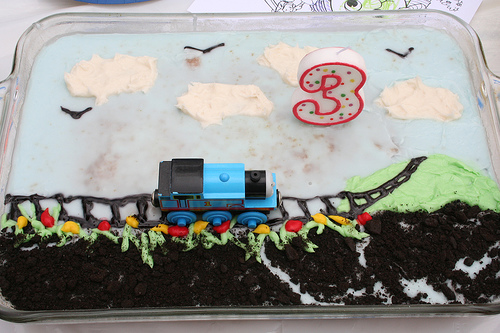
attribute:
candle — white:
[290, 44, 368, 126]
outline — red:
[290, 59, 365, 127]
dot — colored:
[330, 69, 335, 75]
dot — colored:
[347, 100, 354, 107]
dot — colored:
[337, 110, 344, 117]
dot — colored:
[345, 69, 352, 77]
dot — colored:
[308, 109, 315, 115]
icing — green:
[336, 151, 485, 220]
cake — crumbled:
[2, 202, 484, 307]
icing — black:
[4, 154, 427, 228]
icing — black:
[59, 105, 94, 120]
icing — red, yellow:
[12, 206, 372, 235]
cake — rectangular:
[1, 25, 483, 311]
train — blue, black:
[149, 157, 284, 230]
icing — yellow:
[60, 220, 80, 239]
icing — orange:
[96, 219, 111, 231]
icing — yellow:
[190, 217, 210, 233]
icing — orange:
[213, 219, 231, 234]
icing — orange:
[284, 218, 303, 233]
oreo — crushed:
[420, 290, 429, 298]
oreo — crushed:
[461, 255, 474, 267]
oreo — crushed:
[239, 272, 259, 287]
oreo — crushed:
[18, 233, 43, 248]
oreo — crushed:
[307, 224, 317, 240]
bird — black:
[58, 104, 93, 119]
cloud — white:
[372, 74, 467, 124]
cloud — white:
[61, 50, 161, 107]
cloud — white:
[174, 80, 276, 130]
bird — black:
[183, 40, 226, 55]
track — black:
[4, 154, 427, 227]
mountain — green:
[333, 152, 483, 217]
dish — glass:
[1, 9, 483, 330]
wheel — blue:
[163, 209, 196, 231]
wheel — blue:
[199, 210, 232, 227]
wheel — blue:
[233, 212, 268, 231]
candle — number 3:
[288, 49, 368, 128]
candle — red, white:
[290, 41, 367, 132]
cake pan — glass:
[4, 10, 484, 330]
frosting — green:
[338, 158, 484, 223]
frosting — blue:
[26, 40, 471, 192]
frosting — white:
[63, 49, 158, 101]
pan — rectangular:
[3, 9, 483, 330]